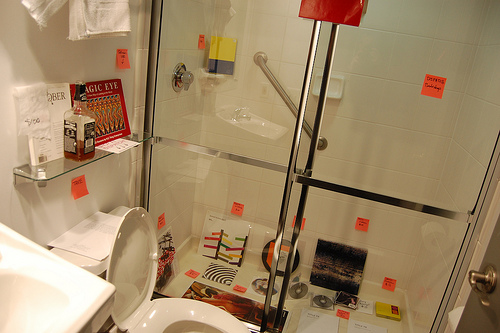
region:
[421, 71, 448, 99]
Sticker on shower door.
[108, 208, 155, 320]
Toilet seat cover.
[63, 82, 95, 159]
A bottle of alcohol.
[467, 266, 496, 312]
A silver door handle.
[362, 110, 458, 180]
White shower tiles.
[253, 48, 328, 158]
Silver handle in the shower.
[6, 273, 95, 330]
Part of the sink.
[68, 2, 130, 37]
Part of a white towel.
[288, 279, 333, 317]
CD's on the floor of the shower.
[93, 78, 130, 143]
Part of a book.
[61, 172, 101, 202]
the post-it is orange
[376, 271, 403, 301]
the post-it is orange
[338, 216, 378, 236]
the post-it is orange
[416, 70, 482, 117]
the post-it is orange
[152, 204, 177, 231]
the post-it is orange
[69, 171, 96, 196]
post-it on the wall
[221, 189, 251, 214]
post-it on the wall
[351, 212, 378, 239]
post-it on the wall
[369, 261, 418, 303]
post-it on the wall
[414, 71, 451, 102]
post-it on the wall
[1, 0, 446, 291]
This is a picture of a bathroom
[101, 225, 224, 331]
This is a picture of a toilet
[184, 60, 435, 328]
This is a shower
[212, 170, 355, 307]
This is a handle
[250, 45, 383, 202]
This is a metal bar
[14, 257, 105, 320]
This is a sink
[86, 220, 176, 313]
The toilet is white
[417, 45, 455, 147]
This is a sticky note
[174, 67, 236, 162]
This is a switch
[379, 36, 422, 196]
This is white tile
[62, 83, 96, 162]
A half filled glass bottle of liquor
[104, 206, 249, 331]
An open toilet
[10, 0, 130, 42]
Hanging white hand towels on the wall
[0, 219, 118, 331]
The corner of a white porcelein sink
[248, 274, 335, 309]
Three CD's inside of a stand up shower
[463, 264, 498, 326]
A nickel plated door knob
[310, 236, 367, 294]
A black and brown record cover inside a shower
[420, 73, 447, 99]
A neon red post-it on a glass shower door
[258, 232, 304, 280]
A record in a clear cover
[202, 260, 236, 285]
A black and white striped CD case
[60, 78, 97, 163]
a half empty bottle of liquour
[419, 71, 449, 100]
orange post-it note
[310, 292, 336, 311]
a CD in a white paper sleeve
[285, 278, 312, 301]
CD in a white paper sleeve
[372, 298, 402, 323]
small yellow box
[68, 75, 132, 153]
red book of magic eye puzzles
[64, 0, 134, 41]
white towel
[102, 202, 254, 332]
an open toilet seat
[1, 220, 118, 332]
the corner of a white sink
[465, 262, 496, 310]
metallic door handle